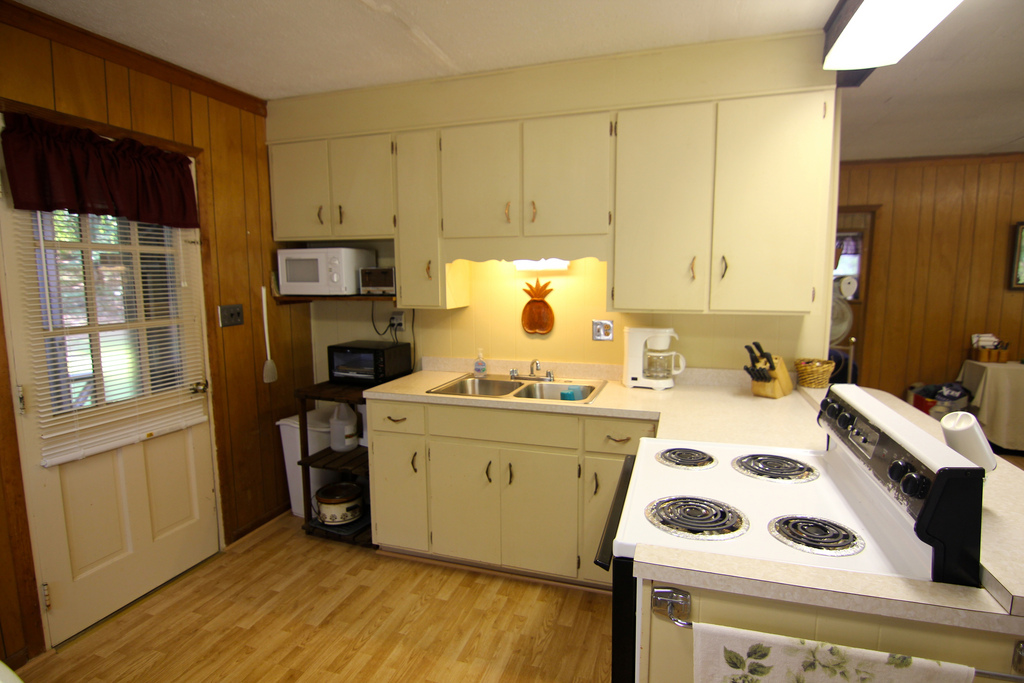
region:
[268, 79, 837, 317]
upper-level wooden kitchen cabinets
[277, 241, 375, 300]
white microwave in cubby hole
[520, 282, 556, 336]
wall decor underneath light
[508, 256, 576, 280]
light over kitchen sink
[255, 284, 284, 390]
fly swatter hanging on wall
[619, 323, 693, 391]
white coffee maker sitting on counter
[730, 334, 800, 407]
kitchen knife set in wooden block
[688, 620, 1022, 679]
kitchen towel hanging on rack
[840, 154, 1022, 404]
wall paneling in living area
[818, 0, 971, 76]
large light fixture on ceiling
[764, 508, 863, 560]
Rear burner on stove.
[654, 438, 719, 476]
Front burner on stove.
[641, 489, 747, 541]
Front burner on stove.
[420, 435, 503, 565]
Cabinet under sink.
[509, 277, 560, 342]
Pineapple above sink.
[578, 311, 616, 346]
Lightswitch near the coffee maker.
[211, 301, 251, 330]
Light switch next to door.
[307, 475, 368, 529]
a brown and beige crock pot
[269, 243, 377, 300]
A small, white, microwave oven.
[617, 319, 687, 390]
a white automatic coffee maker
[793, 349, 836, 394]
a small wicker basket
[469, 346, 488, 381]
A bottle of liquid hand soap.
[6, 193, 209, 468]
White mini-blinds covering the window of the door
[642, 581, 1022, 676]
a metal towel rack attached to the side of the cabinet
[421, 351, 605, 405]
a stainless steel double sided kitchen sink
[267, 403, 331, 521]
A tall, white kitchen trash can.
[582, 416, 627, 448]
handles on a cabinet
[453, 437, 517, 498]
handles on a cabinet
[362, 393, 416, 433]
handle on a cabinet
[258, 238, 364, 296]
microwave on a shelf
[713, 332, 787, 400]
knives on a counter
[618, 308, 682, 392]
coffee pot on counter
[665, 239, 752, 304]
handles on a counter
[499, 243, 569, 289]
light on above sink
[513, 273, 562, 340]
pineapple ceramic above sink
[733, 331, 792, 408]
knife block on counter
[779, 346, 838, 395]
basket on corner of counter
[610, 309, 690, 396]
coffee pot on counter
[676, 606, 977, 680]
towel hanging by oven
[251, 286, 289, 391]
fly swatter hanging on wall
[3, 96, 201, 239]
valence hanging on door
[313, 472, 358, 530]
crockpot on small shelf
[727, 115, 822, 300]
a white wooden cabinet door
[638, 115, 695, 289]
a white wooden cabinet door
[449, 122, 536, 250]
a white wooden cabinet door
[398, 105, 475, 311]
a white wooden cabinet door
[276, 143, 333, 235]
a white wooden cabinet door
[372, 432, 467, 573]
a white wooden cabinet door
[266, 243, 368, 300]
A white microwave on the shelf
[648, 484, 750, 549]
A burner on the stovetop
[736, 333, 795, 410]
A set of knives on the counter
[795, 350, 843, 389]
A basket sitting on the counter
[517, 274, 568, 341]
a fake pineapple on the wall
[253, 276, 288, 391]
A flyswatter on the wall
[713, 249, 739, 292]
A handle of the kitchen cabinet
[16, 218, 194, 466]
The blinds on the kitchen window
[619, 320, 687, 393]
A white coffeepot on the counter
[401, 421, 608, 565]
cabinets under the sink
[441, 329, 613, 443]
sink in the kitchen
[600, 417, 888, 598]
stove above the ground